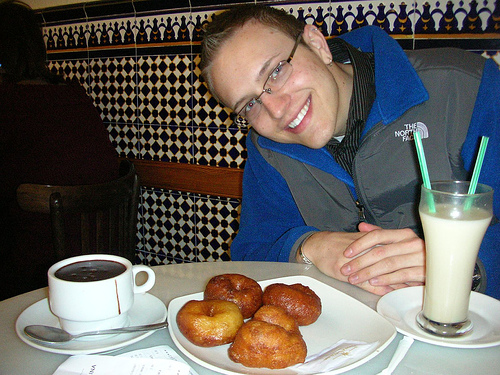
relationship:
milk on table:
[380, 157, 479, 357] [40, 187, 477, 364]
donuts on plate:
[175, 273, 320, 369] [150, 261, 362, 369]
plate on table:
[165, 273, 397, 375] [15, 213, 481, 366]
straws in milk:
[413, 131, 490, 213] [419, 190, 478, 373]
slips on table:
[69, 337, 191, 370] [40, 187, 477, 364]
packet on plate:
[294, 307, 372, 372] [161, 250, 415, 364]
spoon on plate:
[24, 323, 168, 344] [24, 247, 157, 369]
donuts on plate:
[175, 255, 333, 369] [163, 277, 410, 372]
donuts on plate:
[175, 273, 320, 369] [301, 344, 361, 375]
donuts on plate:
[175, 273, 320, 369] [311, 344, 355, 375]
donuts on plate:
[175, 273, 320, 369] [301, 320, 365, 375]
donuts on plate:
[175, 273, 320, 369] [322, 324, 361, 374]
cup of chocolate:
[47, 254, 156, 342] [32, 234, 157, 364]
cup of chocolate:
[47, 254, 156, 342] [41, 251, 162, 375]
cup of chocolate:
[47, 254, 156, 342] [57, 223, 134, 323]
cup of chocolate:
[32, 251, 153, 350] [53, 233, 152, 375]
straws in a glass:
[413, 131, 490, 213] [414, 212, 484, 335]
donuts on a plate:
[175, 273, 320, 369] [282, 364, 358, 375]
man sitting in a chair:
[195, 7, 500, 303] [224, 124, 497, 282]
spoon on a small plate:
[19, 315, 164, 375] [84, 308, 140, 367]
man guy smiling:
[195, 7, 500, 303] [244, 54, 326, 174]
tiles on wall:
[111, 54, 149, 114] [132, 130, 184, 210]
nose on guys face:
[232, 58, 285, 163] [214, 100, 304, 158]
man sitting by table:
[219, 143, 440, 266] [61, 245, 397, 375]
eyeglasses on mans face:
[233, 30, 303, 127] [219, 104, 275, 176]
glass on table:
[390, 192, 495, 323] [341, 346, 465, 375]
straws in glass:
[412, 123, 490, 249] [424, 202, 477, 335]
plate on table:
[184, 260, 354, 370] [32, 295, 202, 352]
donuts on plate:
[175, 273, 320, 369] [321, 300, 375, 375]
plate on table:
[14, 292, 166, 356] [34, 355, 132, 375]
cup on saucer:
[47, 254, 156, 342] [8, 250, 181, 359]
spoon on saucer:
[24, 323, 168, 344] [9, 276, 167, 356]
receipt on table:
[42, 346, 198, 373] [1, 253, 484, 371]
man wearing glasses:
[195, 7, 500, 303] [226, 17, 313, 131]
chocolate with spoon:
[54, 259, 126, 282] [20, 317, 172, 352]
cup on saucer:
[47, 254, 156, 342] [9, 284, 172, 355]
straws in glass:
[413, 131, 490, 213] [415, 168, 477, 334]